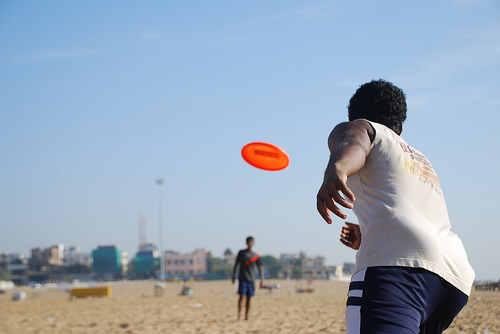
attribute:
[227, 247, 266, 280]
grey shirt — red stripe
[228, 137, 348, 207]
frisbee — orange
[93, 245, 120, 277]
building — pink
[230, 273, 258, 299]
shorts — blue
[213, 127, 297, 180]
frisbee — orange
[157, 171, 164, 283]
pole — white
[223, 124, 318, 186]
frisbee — thrown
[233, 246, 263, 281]
shirt — grey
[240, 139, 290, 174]
frisbee — orange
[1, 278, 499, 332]
beach — sandy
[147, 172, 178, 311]
pole — stands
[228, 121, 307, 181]
frisbee — orange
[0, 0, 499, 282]
sky — blue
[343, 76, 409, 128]
hair — black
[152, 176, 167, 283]
pole — long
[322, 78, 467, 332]
man — leaning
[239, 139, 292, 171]
frisbee — red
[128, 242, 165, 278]
blue/green building — blue , green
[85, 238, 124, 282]
blue/green building — green, blue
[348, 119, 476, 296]
shirt — white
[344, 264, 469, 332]
shorts — blue and white stripes, blue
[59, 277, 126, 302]
box — yellow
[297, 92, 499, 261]
shirt — white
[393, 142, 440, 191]
letters — orange, big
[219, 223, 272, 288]
shirt — grey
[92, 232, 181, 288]
buildings — blue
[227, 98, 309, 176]
frisbee — orange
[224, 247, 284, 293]
shirt — grey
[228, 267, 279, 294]
shorts — blue